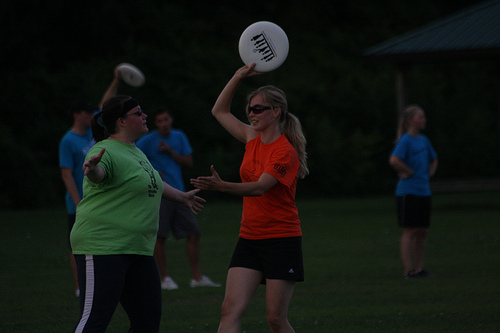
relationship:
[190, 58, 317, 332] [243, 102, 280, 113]
woman wears sunglasses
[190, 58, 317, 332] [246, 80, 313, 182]
woman has hair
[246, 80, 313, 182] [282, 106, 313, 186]
hair in ponytail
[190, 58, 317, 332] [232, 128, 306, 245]
woman wears shirt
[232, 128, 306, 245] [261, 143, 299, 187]
shirt has sleeve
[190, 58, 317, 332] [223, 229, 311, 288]
woman wears shorts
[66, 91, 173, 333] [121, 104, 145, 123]
woman wears sunglasses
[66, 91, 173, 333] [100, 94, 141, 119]
woman wears headband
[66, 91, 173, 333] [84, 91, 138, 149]
woman has hair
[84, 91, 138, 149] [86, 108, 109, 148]
hair in ponytail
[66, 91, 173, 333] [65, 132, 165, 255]
woman wears shirt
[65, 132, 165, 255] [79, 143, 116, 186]
shirt has sleeve